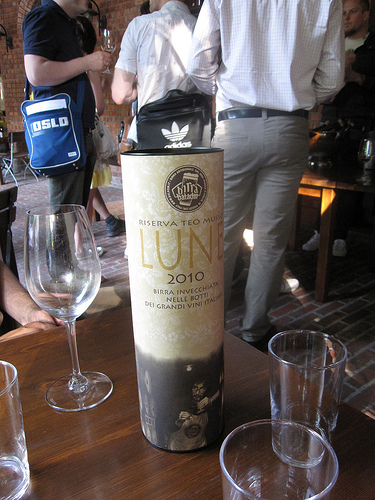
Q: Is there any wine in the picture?
A: Yes, there is wine.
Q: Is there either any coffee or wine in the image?
A: Yes, there is wine.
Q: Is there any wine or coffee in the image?
A: Yes, there is wine.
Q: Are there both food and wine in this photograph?
A: No, there is wine but no food.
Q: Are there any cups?
A: No, there are no cups.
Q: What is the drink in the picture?
A: The drink is wine.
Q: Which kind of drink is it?
A: The drink is wine.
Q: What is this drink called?
A: This is wine.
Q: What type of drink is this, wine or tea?
A: This is wine.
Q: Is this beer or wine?
A: This is wine.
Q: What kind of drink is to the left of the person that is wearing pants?
A: The drink is wine.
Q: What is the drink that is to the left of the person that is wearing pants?
A: The drink is wine.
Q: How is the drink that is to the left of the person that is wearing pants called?
A: The drink is wine.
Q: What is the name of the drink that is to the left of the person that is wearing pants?
A: The drink is wine.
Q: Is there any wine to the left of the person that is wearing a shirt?
A: Yes, there is wine to the left of the person.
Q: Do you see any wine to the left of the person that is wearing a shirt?
A: Yes, there is wine to the left of the person.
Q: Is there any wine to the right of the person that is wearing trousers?
A: No, the wine is to the left of the person.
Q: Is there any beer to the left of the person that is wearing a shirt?
A: No, there is wine to the left of the person.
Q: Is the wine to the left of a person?
A: Yes, the wine is to the left of a person.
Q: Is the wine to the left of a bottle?
A: No, the wine is to the left of a person.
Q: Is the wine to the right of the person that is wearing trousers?
A: No, the wine is to the left of the person.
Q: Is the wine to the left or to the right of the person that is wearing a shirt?
A: The wine is to the left of the person.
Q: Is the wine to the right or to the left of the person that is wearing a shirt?
A: The wine is to the left of the person.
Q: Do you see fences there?
A: No, there are no fences.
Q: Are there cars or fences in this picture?
A: No, there are no fences or cars.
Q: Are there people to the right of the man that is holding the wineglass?
A: Yes, there is a person to the right of the man.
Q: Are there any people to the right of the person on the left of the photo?
A: Yes, there is a person to the right of the man.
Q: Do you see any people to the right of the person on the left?
A: Yes, there is a person to the right of the man.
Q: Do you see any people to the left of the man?
A: No, the person is to the right of the man.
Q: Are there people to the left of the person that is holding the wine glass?
A: No, the person is to the right of the man.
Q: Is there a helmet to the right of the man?
A: No, there is a person to the right of the man.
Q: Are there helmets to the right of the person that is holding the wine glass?
A: No, there is a person to the right of the man.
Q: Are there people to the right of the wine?
A: Yes, there is a person to the right of the wine.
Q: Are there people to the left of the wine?
A: No, the person is to the right of the wine.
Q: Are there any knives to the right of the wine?
A: No, there is a person to the right of the wine.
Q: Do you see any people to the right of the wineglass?
A: Yes, there is a person to the right of the wineglass.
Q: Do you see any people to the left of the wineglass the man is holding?
A: No, the person is to the right of the wineglass.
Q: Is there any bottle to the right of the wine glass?
A: No, there is a person to the right of the wine glass.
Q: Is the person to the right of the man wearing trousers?
A: Yes, the person is wearing trousers.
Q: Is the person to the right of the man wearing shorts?
A: No, the person is wearing trousers.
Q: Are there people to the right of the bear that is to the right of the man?
A: Yes, there is a person to the right of the bear.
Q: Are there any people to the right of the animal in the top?
A: Yes, there is a person to the right of the bear.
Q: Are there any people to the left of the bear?
A: No, the person is to the right of the bear.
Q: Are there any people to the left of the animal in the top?
A: No, the person is to the right of the bear.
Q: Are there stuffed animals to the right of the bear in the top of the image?
A: No, there is a person to the right of the bear.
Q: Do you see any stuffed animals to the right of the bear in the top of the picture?
A: No, there is a person to the right of the bear.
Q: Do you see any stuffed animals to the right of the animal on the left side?
A: No, there is a person to the right of the bear.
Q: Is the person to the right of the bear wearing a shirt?
A: Yes, the person is wearing a shirt.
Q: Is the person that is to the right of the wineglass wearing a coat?
A: No, the person is wearing a shirt.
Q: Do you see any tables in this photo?
A: Yes, there is a table.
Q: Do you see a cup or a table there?
A: Yes, there is a table.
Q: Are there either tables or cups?
A: Yes, there is a table.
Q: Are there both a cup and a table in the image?
A: No, there is a table but no cups.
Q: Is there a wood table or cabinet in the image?
A: Yes, there is a wood table.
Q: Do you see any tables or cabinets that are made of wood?
A: Yes, the table is made of wood.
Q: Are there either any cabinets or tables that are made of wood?
A: Yes, the table is made of wood.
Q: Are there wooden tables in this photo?
A: Yes, there is a wood table.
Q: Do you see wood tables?
A: Yes, there is a wood table.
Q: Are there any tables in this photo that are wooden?
A: Yes, there is a table that is wooden.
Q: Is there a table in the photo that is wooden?
A: Yes, there is a table that is wooden.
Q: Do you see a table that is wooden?
A: Yes, there is a table that is wooden.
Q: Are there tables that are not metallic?
A: Yes, there is a wooden table.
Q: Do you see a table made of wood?
A: Yes, there is a table that is made of wood.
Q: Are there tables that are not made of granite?
A: Yes, there is a table that is made of wood.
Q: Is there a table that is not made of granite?
A: Yes, there is a table that is made of wood.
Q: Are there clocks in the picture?
A: No, there are no clocks.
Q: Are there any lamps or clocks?
A: No, there are no clocks or lamps.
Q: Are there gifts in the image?
A: No, there are no gifts.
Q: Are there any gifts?
A: No, there are no gifts.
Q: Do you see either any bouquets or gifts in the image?
A: No, there are no gifts or bouquets.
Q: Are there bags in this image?
A: Yes, there is a bag.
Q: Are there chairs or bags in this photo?
A: Yes, there is a bag.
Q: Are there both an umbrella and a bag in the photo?
A: No, there is a bag but no umbrellas.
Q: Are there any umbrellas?
A: No, there are no umbrellas.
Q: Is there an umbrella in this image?
A: No, there are no umbrellas.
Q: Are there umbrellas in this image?
A: No, there are no umbrellas.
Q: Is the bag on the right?
A: No, the bag is on the left of the image.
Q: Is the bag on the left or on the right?
A: The bag is on the left of the image.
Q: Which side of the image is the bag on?
A: The bag is on the left of the image.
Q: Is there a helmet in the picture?
A: No, there are no helmets.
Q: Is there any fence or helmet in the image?
A: No, there are no helmets or fences.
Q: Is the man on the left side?
A: Yes, the man is on the left of the image.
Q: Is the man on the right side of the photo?
A: No, the man is on the left of the image.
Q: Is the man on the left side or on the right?
A: The man is on the left of the image.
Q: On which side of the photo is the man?
A: The man is on the left of the image.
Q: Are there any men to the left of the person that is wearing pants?
A: Yes, there is a man to the left of the person.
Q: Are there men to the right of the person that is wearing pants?
A: No, the man is to the left of the person.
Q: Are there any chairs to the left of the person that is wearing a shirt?
A: No, there is a man to the left of the person.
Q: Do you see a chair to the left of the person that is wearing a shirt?
A: No, there is a man to the left of the person.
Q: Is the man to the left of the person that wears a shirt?
A: Yes, the man is to the left of the person.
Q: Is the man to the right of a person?
A: No, the man is to the left of a person.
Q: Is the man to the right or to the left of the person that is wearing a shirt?
A: The man is to the left of the person.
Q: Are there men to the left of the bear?
A: Yes, there is a man to the left of the bear.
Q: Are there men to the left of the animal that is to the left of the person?
A: Yes, there is a man to the left of the bear.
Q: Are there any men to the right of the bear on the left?
A: No, the man is to the left of the bear.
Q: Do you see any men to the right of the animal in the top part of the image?
A: No, the man is to the left of the bear.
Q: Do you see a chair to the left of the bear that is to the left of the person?
A: No, there is a man to the left of the bear.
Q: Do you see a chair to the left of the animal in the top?
A: No, there is a man to the left of the bear.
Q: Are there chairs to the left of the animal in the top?
A: No, there is a man to the left of the bear.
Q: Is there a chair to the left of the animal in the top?
A: No, there is a man to the left of the bear.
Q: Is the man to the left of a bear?
A: Yes, the man is to the left of a bear.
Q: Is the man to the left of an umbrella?
A: No, the man is to the left of a bear.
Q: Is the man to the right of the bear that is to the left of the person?
A: No, the man is to the left of the bear.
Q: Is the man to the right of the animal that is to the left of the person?
A: No, the man is to the left of the bear.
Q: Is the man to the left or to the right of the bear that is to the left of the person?
A: The man is to the left of the bear.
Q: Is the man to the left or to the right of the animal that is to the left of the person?
A: The man is to the left of the bear.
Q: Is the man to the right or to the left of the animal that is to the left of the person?
A: The man is to the left of the bear.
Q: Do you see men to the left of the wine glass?
A: Yes, there is a man to the left of the wine glass.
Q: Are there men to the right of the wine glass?
A: No, the man is to the left of the wine glass.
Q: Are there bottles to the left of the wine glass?
A: No, there is a man to the left of the wine glass.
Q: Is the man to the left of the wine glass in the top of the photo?
A: Yes, the man is to the left of the wineglass.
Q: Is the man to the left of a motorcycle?
A: No, the man is to the left of the wineglass.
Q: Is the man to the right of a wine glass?
A: No, the man is to the left of a wine glass.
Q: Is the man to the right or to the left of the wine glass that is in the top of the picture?
A: The man is to the left of the wine glass.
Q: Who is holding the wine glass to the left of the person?
A: The man is holding the wineglass.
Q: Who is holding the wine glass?
A: The man is holding the wineglass.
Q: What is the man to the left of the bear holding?
A: The man is holding the wine glass.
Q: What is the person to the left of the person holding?
A: The man is holding the wine glass.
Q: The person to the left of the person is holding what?
A: The man is holding the wine glass.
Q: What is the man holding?
A: The man is holding the wine glass.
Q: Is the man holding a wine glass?
A: Yes, the man is holding a wine glass.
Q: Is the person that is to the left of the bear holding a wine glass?
A: Yes, the man is holding a wine glass.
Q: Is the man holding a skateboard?
A: No, the man is holding a wine glass.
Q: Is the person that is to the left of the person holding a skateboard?
A: No, the man is holding a wine glass.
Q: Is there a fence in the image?
A: No, there are no fences.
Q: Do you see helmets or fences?
A: No, there are no fences or helmets.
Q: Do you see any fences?
A: No, there are no fences.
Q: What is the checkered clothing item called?
A: The clothing item is a shirt.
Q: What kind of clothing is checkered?
A: The clothing is a shirt.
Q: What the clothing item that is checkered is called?
A: The clothing item is a shirt.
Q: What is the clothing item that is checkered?
A: The clothing item is a shirt.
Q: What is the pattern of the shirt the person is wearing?
A: The shirt is checkered.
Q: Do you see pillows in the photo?
A: No, there are no pillows.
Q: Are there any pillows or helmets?
A: No, there are no pillows or helmets.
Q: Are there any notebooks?
A: No, there are no notebooks.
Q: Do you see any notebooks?
A: No, there are no notebooks.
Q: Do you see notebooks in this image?
A: No, there are no notebooks.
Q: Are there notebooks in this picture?
A: No, there are no notebooks.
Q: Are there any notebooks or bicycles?
A: No, there are no notebooks or bicycles.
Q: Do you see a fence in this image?
A: No, there are no fences.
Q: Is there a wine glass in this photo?
A: Yes, there is a wine glass.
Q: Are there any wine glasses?
A: Yes, there is a wine glass.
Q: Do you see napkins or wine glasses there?
A: Yes, there is a wine glass.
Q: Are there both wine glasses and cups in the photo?
A: No, there is a wine glass but no cups.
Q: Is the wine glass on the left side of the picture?
A: Yes, the wine glass is on the left of the image.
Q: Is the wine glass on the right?
A: No, the wine glass is on the left of the image.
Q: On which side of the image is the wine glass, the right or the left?
A: The wine glass is on the left of the image.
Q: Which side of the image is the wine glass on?
A: The wine glass is on the left of the image.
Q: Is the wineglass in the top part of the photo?
A: Yes, the wineglass is in the top of the image.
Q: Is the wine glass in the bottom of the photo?
A: No, the wine glass is in the top of the image.